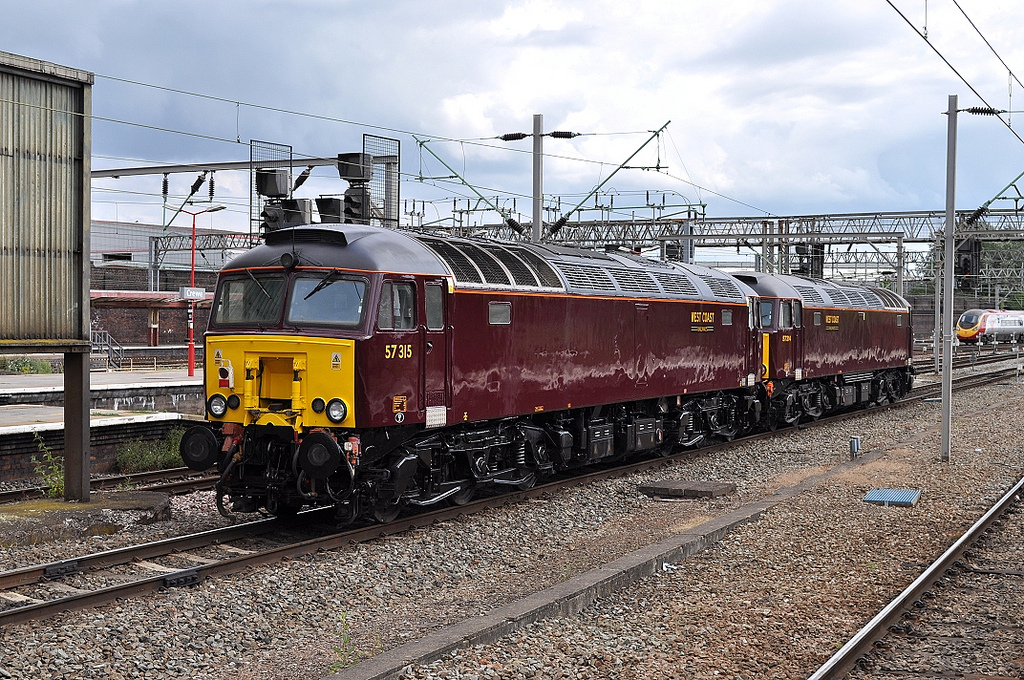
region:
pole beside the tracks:
[930, 137, 984, 501]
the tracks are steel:
[87, 520, 335, 609]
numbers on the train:
[381, 339, 423, 360]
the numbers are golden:
[368, 333, 423, 366]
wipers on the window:
[238, 264, 360, 321]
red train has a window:
[371, 278, 397, 326]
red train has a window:
[210, 278, 290, 333]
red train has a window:
[425, 275, 444, 326]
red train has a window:
[374, 275, 414, 329]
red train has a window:
[485, 300, 506, 321]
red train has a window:
[379, 283, 393, 329]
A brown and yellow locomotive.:
[204, 223, 914, 514]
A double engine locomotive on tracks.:
[0, 206, 1023, 621]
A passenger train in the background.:
[960, 308, 1022, 346]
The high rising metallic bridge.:
[420, 209, 1021, 276]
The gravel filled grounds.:
[0, 368, 1023, 676]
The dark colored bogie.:
[195, 365, 920, 525]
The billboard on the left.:
[0, 52, 93, 348]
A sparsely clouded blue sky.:
[6, 1, 1022, 252]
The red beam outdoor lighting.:
[167, 203, 226, 380]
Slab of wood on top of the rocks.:
[630, 468, 747, 501]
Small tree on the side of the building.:
[0, 416, 86, 516]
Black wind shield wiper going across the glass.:
[287, 263, 333, 305]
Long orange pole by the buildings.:
[164, 198, 207, 382]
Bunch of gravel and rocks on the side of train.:
[531, 633, 579, 662]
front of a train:
[200, 251, 365, 451]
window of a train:
[219, 276, 281, 322]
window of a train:
[383, 278, 412, 324]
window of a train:
[427, 283, 441, 325]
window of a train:
[757, 305, 770, 328]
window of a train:
[781, 303, 797, 323]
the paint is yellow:
[200, 334, 353, 424]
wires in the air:
[93, 74, 777, 226]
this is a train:
[166, 172, 713, 521]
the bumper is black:
[198, 420, 399, 490]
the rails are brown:
[40, 526, 272, 635]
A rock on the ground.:
[316, 576, 329, 581]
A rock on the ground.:
[329, 569, 337, 577]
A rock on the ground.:
[353, 569, 358, 576]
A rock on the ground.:
[458, 551, 468, 559]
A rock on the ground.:
[470, 539, 478, 544]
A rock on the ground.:
[558, 631, 565, 638]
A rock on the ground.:
[517, 655, 527, 662]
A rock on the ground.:
[499, 656, 513, 673]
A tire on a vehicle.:
[433, 447, 485, 496]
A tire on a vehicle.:
[536, 438, 572, 471]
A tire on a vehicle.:
[574, 424, 613, 466]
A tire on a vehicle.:
[705, 405, 740, 435]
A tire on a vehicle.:
[770, 393, 813, 428]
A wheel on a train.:
[404, 453, 468, 498]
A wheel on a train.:
[470, 438, 531, 487]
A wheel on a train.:
[769, 397, 793, 416]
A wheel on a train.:
[806, 380, 839, 420]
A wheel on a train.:
[874, 381, 904, 413]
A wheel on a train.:
[896, 371, 915, 392]